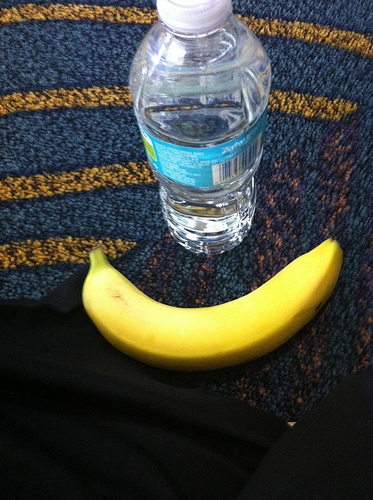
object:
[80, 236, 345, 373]
banana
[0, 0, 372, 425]
carpet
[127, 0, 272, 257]
bottle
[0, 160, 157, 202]
stripe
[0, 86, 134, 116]
stripe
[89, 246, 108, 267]
tip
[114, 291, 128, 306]
bruise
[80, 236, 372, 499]
material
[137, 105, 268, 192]
label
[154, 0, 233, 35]
cap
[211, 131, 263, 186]
barcode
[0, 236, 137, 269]
stripe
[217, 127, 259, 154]
zephyrhills